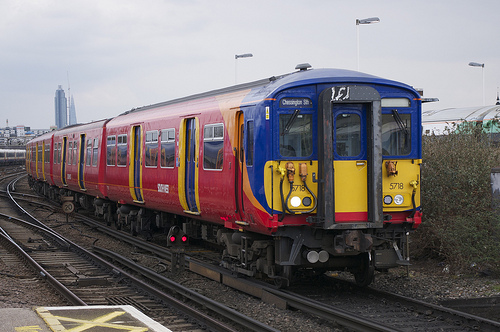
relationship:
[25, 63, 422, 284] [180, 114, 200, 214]
train has door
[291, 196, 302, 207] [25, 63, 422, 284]
headlights on train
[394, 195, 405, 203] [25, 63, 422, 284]
headlights on train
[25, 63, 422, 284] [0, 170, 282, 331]
train next to tracks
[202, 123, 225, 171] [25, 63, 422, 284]
windows on train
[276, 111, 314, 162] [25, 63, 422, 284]
windows on train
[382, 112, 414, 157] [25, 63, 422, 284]
windows on train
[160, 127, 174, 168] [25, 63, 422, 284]
windows on train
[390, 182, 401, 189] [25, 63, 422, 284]
numbers on train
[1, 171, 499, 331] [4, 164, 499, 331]
train tracks on ground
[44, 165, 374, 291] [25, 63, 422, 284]
train tracks are under train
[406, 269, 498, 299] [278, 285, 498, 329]
gravel next to train tracks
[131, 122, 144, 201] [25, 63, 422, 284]
door on side of train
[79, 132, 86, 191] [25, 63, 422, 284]
door on side of train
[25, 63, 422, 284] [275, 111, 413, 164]
train has front windows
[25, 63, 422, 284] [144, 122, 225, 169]
train has side windows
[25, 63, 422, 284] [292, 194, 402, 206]
train has headlights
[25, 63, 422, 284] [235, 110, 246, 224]
train has front door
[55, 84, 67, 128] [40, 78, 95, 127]
building in distance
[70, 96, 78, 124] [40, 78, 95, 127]
building in distance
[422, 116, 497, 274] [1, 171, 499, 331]
bushes next to train tracks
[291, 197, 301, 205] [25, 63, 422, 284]
headlight on train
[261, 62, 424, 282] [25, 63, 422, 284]
front of moving train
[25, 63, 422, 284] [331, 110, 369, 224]
train has entrance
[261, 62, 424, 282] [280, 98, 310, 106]
train front has writing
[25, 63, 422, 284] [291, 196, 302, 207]
train has light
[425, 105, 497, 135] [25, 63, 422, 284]
structure next to train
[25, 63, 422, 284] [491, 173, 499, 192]
train next to structure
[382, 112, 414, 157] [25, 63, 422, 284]
windows are on train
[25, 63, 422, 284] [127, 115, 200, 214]
train has side doors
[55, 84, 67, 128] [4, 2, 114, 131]
building in background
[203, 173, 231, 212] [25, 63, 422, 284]
red on train